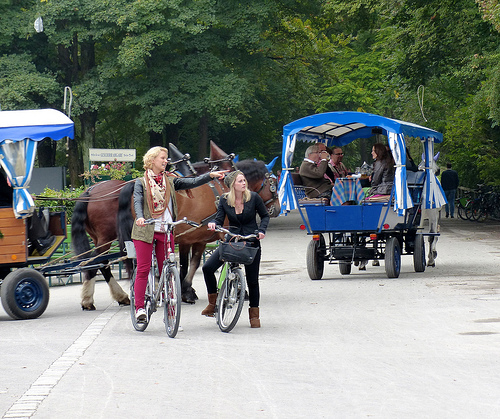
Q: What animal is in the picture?
A: Horse.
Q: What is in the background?
A: Trees.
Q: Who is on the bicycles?
A: Two women.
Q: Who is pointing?
A: Woman on left.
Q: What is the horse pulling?
A: A carriage.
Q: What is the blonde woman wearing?
A: Pink jeans and a white shirt.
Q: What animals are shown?
A: Horses.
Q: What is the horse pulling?
A: A carriage.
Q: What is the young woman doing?
A: Pointing at something.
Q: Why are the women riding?
A: Bicycles.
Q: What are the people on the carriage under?
A: A blue tarp.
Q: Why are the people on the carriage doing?
A: Taking a ride.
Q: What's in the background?
A: Trees.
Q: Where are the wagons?
A: On the road.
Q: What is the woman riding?
A: Bicycle.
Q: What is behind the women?
A: Wagon.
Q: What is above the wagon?
A: Covering.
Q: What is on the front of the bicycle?
A: Basket.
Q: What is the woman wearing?
A: A hat.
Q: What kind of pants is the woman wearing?
A: Pink pants.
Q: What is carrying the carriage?
A: Horse.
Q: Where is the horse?
A: Sidewalk.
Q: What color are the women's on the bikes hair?
A: Blond.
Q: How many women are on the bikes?
A: 2.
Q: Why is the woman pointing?
A: To show something to the other woman.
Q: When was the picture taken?
A: During daytime.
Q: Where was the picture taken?
A: In a park.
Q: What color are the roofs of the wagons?
A: Blue and white.